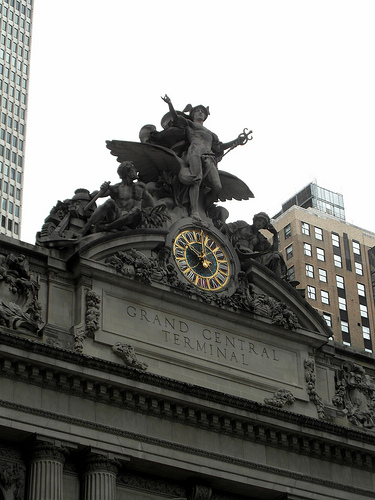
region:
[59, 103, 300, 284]
Complex statue with many people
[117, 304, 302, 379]
Picture taken at Grand Central Terminal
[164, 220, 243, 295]
A clock face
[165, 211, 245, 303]
The clock is round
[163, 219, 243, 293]
The clock is made of gold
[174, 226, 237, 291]
The clock's numbers are roman numerals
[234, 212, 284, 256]
Statue resting on its left fist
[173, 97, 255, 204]
Statue holding trident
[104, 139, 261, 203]
Statue has wings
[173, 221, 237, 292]
clock on the building.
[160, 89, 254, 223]
Statue of a man.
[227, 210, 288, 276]
Statue of a woman.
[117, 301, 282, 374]
Lettering on the building.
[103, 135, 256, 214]
wings on the statue.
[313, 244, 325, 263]
Window in the building.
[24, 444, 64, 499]
column on the building.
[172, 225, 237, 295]
black and gold hands on clock.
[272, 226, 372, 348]
Brown brick on the building.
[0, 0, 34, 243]
Skyscraper in the background.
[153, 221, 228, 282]
clock on the tower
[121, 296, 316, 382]
sign for grand central terminal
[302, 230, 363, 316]
windows on the building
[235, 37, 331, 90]
the sky is white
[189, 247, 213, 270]
hands on the clock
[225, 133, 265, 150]
hands of the statue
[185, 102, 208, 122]
head of the statue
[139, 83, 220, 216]
statue on the top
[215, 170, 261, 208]
wings of the statue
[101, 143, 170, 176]
wing of the statue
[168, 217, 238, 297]
Small black and gold clock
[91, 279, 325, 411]
Black sign on front of building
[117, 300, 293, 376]
Carved letters on the sign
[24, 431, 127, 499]
Two fancy grey columns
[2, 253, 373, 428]
Small designs on front of store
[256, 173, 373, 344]
Tall building with alot of windows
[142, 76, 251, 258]
Statue of angel on top of tower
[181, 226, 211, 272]
Black and gold hands on clock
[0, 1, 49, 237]
Tall skyscraper in the corner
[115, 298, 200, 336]
Carved word 'Grand'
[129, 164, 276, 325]
Clock on the building.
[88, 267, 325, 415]
Words on the building.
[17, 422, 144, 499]
Columns on the building.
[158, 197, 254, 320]
Gold filigree on the clock.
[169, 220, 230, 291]
Hands on the clock.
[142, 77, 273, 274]
Statue on the building.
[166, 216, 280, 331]
Roman numerals on the clock.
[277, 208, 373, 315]
Windows on the building.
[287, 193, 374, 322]
Bricks on the building.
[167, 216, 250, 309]
Gold on the clock.